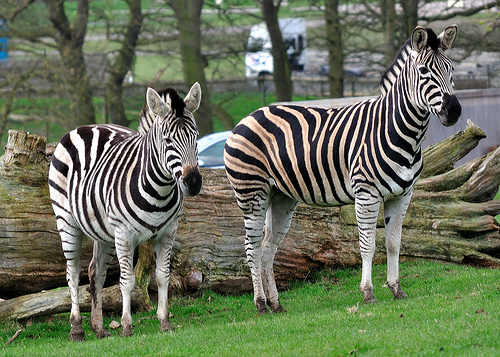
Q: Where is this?
A: This is at the zoo.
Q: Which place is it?
A: It is a zoo.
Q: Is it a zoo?
A: Yes, it is a zoo.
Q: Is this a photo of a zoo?
A: Yes, it is showing a zoo.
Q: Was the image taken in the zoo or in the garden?
A: It was taken at the zoo.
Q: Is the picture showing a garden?
A: No, the picture is showing a zoo.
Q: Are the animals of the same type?
A: Yes, all the animals are zebras.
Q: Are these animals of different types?
A: No, all the animals are zebras.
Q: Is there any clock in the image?
A: No, there are no clocks.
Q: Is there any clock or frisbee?
A: No, there are no clocks or frisbees.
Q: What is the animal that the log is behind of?
A: The animal is a zebra.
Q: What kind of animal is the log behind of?
A: The log is behind the zebra.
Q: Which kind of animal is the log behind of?
A: The log is behind the zebra.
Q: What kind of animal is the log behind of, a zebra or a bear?
A: The log is behind a zebra.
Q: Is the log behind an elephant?
A: No, the log is behind the zebra.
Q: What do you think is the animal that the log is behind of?
A: The animal is a zebra.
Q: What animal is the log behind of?
A: The log is behind the zebra.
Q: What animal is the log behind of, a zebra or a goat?
A: The log is behind a zebra.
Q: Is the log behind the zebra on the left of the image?
A: Yes, the log is behind the zebra.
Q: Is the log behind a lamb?
A: No, the log is behind the zebra.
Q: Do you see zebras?
A: Yes, there is a zebra.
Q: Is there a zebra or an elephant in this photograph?
A: Yes, there is a zebra.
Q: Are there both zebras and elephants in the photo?
A: No, there is a zebra but no elephants.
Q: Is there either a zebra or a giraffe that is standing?
A: Yes, the zebra is standing.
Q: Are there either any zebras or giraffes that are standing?
A: Yes, the zebra is standing.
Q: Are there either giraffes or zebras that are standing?
A: Yes, the zebra is standing.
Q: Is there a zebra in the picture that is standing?
A: Yes, there is a zebra that is standing.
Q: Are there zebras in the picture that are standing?
A: Yes, there is a zebra that is standing.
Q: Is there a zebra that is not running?
A: Yes, there is a zebra that is standing.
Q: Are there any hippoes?
A: No, there are no hippoes.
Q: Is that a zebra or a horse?
A: That is a zebra.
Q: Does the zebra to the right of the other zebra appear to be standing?
A: Yes, the zebra is standing.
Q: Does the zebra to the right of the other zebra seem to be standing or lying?
A: The zebra is standing.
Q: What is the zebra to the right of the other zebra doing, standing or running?
A: The zebra is standing.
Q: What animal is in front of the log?
A: The zebra is in front of the log.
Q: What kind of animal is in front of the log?
A: The animal is a zebra.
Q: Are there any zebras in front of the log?
A: Yes, there is a zebra in front of the log.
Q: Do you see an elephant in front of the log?
A: No, there is a zebra in front of the log.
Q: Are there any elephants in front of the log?
A: No, there is a zebra in front of the log.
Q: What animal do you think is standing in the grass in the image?
A: The zebra is standing in the grass.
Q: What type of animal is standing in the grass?
A: The animal is a zebra.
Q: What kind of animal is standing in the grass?
A: The animal is a zebra.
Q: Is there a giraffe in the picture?
A: No, there are no giraffes.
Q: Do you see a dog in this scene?
A: No, there are no dogs.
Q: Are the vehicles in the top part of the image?
A: Yes, the vehicles are in the top of the image.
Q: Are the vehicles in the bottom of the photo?
A: No, the vehicles are in the top of the image.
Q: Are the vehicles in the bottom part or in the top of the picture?
A: The vehicles are in the top of the image.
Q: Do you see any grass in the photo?
A: Yes, there is grass.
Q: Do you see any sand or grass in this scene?
A: Yes, there is grass.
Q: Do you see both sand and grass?
A: No, there is grass but no sand.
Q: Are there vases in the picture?
A: No, there are no vases.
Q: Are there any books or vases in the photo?
A: No, there are no vases or books.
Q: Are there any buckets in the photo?
A: No, there are no buckets.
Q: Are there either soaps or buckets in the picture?
A: No, there are no buckets or soaps.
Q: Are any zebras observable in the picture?
A: Yes, there is a zebra.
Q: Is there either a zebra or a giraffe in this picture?
A: Yes, there is a zebra.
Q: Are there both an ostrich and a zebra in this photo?
A: No, there is a zebra but no ostriches.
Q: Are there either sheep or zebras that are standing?
A: Yes, the zebra is standing.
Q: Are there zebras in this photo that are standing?
A: Yes, there is a zebra that is standing.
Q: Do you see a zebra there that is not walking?
A: Yes, there is a zebra that is standing .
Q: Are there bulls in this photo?
A: No, there are no bulls.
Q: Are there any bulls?
A: No, there are no bulls.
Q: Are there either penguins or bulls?
A: No, there are no bulls or penguins.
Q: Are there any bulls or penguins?
A: No, there are no bulls or penguins.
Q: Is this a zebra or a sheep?
A: This is a zebra.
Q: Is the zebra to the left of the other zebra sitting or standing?
A: The zebra is standing.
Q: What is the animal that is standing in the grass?
A: The animal is a zebra.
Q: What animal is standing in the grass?
A: The animal is a zebra.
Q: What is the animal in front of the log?
A: The animal is a zebra.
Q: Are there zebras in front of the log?
A: Yes, there is a zebra in front of the log.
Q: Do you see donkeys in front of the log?
A: No, there is a zebra in front of the log.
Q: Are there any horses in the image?
A: No, there are no horses.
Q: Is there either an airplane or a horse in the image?
A: No, there are no horses or airplanes.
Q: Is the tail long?
A: Yes, the tail is long.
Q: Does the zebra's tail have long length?
A: Yes, the tail is long.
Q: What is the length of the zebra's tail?
A: The tail is long.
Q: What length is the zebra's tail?
A: The tail is long.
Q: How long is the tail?
A: The tail is long.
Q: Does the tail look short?
A: No, the tail is long.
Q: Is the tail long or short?
A: The tail is long.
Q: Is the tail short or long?
A: The tail is long.